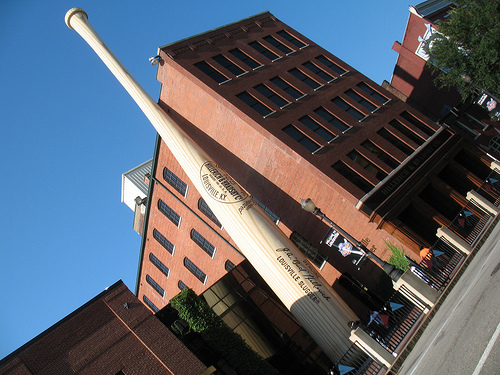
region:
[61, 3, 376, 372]
a large wooden baseball bat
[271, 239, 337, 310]
writing on the baseball bat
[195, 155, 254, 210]
the label of the baseball bat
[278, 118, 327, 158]
a window on the building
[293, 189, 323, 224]
a street light on the pole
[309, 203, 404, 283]
a black metal lamp post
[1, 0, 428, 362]
a clear blue sky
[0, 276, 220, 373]
a red brick building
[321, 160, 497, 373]
a black metal fence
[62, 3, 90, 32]
the knob of the baseball bat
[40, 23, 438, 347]
a building with a large baseball bat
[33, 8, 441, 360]
this is an unsual picture of a unique building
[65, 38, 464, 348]
Louisville Slugger Museum and Factory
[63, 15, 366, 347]
this building honors Babe Ruth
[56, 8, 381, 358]
this is the largest bat in the world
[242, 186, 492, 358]
a fence in front of the building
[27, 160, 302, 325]
the building is red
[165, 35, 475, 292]
this building is located near the street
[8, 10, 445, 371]
this picture is slanted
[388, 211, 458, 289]
people at the museum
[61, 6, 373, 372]
a giant baseball bat leaning on a high rise building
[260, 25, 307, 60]
the windows of a building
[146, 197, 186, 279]
the windows of a building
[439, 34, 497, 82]
the leaves of a tree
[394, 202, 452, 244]
the door way to a buildig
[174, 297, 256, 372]
a vine growing on the side of a building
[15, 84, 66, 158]
the clear blue sky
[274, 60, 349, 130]
the windows of a building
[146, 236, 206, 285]
the windows of a building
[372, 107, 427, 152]
the windows of a building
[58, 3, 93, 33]
the knob of a baseball bat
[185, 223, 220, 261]
a window on the building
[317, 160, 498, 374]
a black metal gate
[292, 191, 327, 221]
a street lamp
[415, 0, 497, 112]
a leafy green tree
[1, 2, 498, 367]
Photo is at a side angle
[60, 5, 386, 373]
A large baseball bat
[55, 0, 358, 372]
Bat is made out of wood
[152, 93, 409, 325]
Bat is casting a shadow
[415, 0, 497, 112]
A tree in the background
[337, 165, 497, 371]
A fence in the foreground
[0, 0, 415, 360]
The sky is clear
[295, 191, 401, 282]
A street lamp in the foreground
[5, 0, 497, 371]
Photo was taken outdoors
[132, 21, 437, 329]
Buildings windows are dark colored